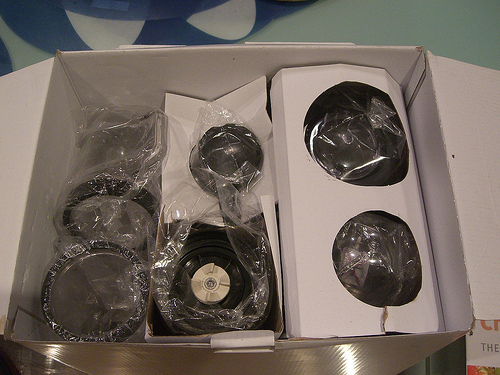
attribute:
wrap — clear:
[68, 105, 165, 246]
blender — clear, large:
[166, 240, 269, 318]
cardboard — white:
[163, 74, 277, 226]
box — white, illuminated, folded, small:
[1, 44, 499, 372]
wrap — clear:
[317, 99, 397, 168]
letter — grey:
[480, 341, 487, 352]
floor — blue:
[320, 1, 499, 42]